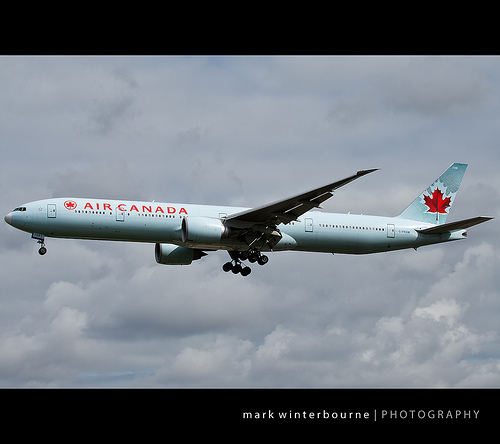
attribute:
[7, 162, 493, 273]
plane — red